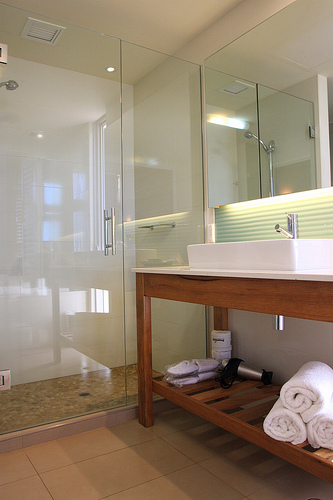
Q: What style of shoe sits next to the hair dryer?
A: Slippers.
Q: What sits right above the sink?
A: Faucet.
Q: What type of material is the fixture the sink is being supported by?
A: Wood.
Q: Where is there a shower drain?
A: In the shower.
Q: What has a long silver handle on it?
A: Shower door.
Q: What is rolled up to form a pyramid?
A: Towels.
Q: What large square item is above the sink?
A: Mirror.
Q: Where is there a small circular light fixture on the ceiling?
A: Shower.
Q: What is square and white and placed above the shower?
A: Air vent,.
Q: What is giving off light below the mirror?
A: Light bar.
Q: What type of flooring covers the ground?
A: Beige tile.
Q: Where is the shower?
A: Next to the vanity.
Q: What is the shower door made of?
A: Glass.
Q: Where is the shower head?
A: In the shower.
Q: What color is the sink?
A: White.